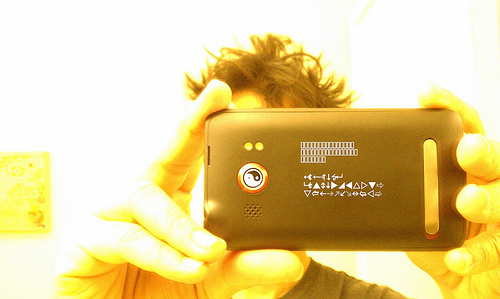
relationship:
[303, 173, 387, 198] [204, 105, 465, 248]
symbol on cellphone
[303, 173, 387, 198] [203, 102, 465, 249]
symbol on cell phone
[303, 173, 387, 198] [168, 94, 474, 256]
symbol on cell phone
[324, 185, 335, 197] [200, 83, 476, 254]
symbol on cellphone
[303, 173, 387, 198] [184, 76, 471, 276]
symbol on cellphone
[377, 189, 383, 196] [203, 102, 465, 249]
white symbol on cell phone